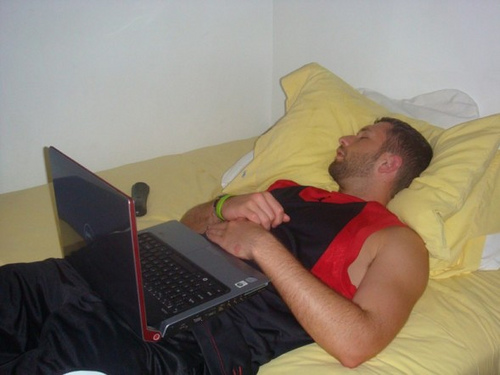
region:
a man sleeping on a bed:
[3, 116, 433, 373]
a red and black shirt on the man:
[176, 179, 409, 374]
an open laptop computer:
[49, 145, 271, 342]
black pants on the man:
[0, 254, 210, 373]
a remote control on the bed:
[131, 181, 151, 215]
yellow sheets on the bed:
[1, 110, 496, 372]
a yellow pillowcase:
[223, 62, 498, 275]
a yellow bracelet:
[214, 194, 235, 221]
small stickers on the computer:
[236, 274, 257, 290]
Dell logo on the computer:
[81, 223, 93, 247]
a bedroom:
[8, 38, 488, 373]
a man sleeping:
[11, 97, 498, 373]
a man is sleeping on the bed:
[13, 98, 493, 373]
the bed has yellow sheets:
[14, 74, 499, 371]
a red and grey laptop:
[44, 117, 271, 334]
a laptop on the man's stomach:
[31, 112, 441, 364]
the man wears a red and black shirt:
[206, 108, 461, 349]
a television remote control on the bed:
[119, 162, 191, 231]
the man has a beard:
[28, 77, 498, 351]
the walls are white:
[30, 7, 496, 209]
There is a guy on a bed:
[48, 77, 481, 367]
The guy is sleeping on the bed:
[54, 83, 463, 370]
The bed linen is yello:
[61, 61, 468, 371]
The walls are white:
[25, 9, 474, 364]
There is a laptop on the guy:
[75, 119, 441, 371]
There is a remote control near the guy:
[35, 119, 444, 371]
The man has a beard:
[99, 121, 478, 360]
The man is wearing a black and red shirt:
[103, 117, 455, 373]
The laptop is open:
[13, 50, 310, 356]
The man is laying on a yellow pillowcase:
[149, 79, 455, 307]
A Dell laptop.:
[44, 150, 276, 333]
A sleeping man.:
[308, 124, 453, 190]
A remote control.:
[126, 172, 152, 217]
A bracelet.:
[213, 188, 234, 221]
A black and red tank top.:
[269, 170, 446, 332]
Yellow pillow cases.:
[292, 62, 498, 248]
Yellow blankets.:
[2, 184, 458, 372]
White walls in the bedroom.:
[32, 4, 479, 112]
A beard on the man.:
[336, 144, 373, 181]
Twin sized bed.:
[10, 64, 463, 371]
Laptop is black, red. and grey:
[41, 144, 270, 347]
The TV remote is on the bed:
[127, 180, 150, 221]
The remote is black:
[128, 181, 148, 217]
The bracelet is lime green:
[212, 188, 244, 226]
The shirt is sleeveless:
[188, 180, 405, 371]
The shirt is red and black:
[183, 178, 408, 373]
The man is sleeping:
[1, 118, 430, 373]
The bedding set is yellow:
[1, 64, 496, 373]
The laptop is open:
[46, 143, 269, 343]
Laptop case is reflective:
[51, 142, 144, 347]